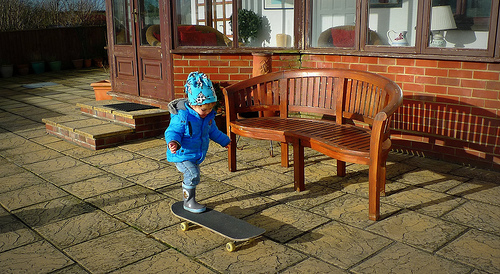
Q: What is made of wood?
A: Bench.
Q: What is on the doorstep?
A: Stairs.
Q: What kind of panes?
A: Glass.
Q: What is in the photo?
A: Child.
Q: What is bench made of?
A: Wood.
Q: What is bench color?
A: Brown.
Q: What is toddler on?
A: Skateboard.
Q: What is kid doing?
A: Skateboard.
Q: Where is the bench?
A: Next to the building.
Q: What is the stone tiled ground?
A: Clean.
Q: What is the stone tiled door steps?
A: Clean.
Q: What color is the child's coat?
A: Blue.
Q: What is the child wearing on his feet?
A: Boots.